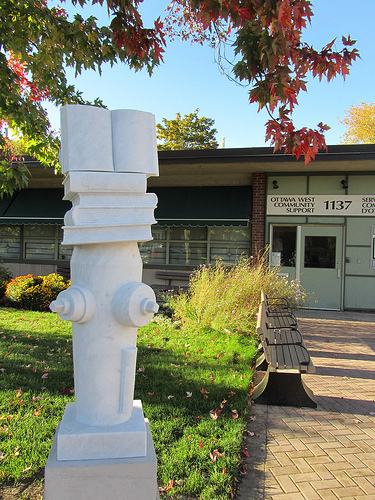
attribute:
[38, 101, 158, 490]
statue — white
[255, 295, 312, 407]
benches — wooden, empty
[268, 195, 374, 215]
sign — white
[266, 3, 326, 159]
leaves — red, yellow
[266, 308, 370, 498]
sidewalk — brick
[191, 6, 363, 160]
foliage — colorful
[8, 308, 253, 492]
grass — green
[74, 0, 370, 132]
sky — blue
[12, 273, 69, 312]
shrub — green